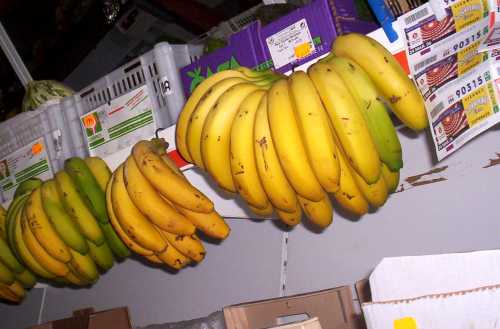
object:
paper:
[402, 0, 500, 163]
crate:
[55, 41, 203, 170]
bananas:
[330, 31, 427, 132]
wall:
[1, 125, 500, 329]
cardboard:
[178, 0, 380, 100]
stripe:
[168, 149, 191, 170]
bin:
[71, 40, 204, 160]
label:
[79, 87, 157, 159]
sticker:
[390, 316, 419, 329]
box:
[360, 250, 500, 329]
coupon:
[396, 0, 500, 164]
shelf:
[1, 20, 500, 205]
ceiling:
[0, 0, 278, 81]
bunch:
[3, 32, 429, 304]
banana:
[64, 155, 108, 224]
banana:
[267, 76, 326, 201]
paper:
[397, 0, 500, 162]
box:
[179, 0, 381, 100]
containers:
[0, 42, 205, 202]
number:
[456, 90, 461, 99]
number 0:
[461, 87, 466, 95]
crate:
[0, 93, 77, 204]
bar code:
[430, 102, 445, 119]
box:
[220, 282, 369, 329]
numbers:
[477, 76, 482, 86]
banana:
[130, 139, 216, 213]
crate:
[58, 40, 203, 163]